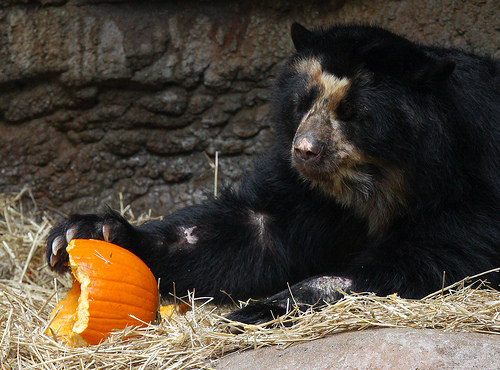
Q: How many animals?
A: One.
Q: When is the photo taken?
A: Daytime.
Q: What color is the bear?
A: Black.